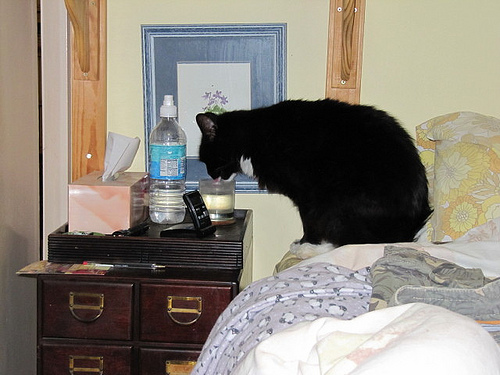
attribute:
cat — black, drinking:
[195, 101, 434, 245]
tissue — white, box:
[96, 127, 146, 191]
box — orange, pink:
[63, 173, 150, 237]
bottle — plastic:
[150, 91, 188, 234]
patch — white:
[236, 152, 263, 184]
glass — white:
[199, 178, 237, 221]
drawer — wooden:
[35, 274, 139, 349]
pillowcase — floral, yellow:
[416, 112, 499, 241]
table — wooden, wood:
[34, 267, 240, 372]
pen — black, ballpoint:
[107, 259, 170, 273]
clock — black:
[179, 188, 217, 234]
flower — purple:
[201, 88, 233, 111]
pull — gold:
[68, 293, 111, 323]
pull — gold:
[167, 296, 207, 326]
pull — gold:
[67, 354, 105, 374]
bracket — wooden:
[69, 2, 109, 178]